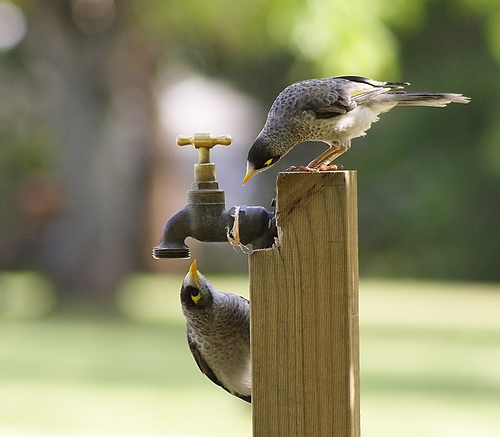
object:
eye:
[191, 288, 200, 297]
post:
[248, 170, 360, 437]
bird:
[180, 259, 250, 405]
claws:
[285, 164, 344, 172]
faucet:
[151, 133, 277, 260]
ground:
[382, 330, 469, 410]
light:
[349, 367, 354, 414]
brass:
[153, 133, 278, 260]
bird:
[243, 76, 472, 186]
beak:
[243, 173, 254, 185]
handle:
[176, 133, 232, 181]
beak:
[189, 259, 196, 272]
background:
[0, 0, 500, 318]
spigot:
[176, 133, 232, 181]